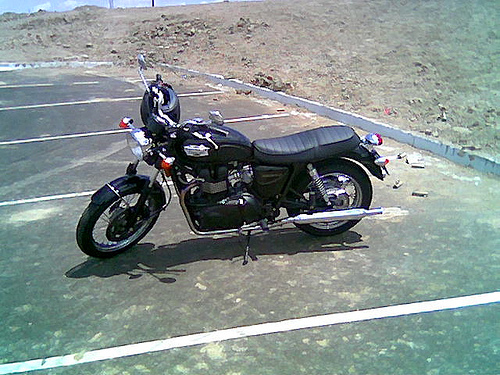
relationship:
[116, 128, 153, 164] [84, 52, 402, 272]
headlight on the bike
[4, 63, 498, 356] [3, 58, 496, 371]
lines in lot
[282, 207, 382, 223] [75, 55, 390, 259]
muffler on bike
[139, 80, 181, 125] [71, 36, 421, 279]
helmet hanging on motorcycle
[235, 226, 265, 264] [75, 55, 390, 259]
kickstand held up by bike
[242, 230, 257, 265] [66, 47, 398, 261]
kickstand holding up bike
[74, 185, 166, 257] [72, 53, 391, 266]
front tire mounted on motorcycle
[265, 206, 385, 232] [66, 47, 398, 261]
muffler on bike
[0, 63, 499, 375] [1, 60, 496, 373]
lines on pavement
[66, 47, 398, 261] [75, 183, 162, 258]
bike has front tire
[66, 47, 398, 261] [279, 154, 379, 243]
bike has tire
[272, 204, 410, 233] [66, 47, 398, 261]
exhaust pipe on bike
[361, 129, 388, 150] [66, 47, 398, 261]
light on bike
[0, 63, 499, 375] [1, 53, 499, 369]
lines on parking lot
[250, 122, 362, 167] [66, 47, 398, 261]
seat on bike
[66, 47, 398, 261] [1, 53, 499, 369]
bike on parking lot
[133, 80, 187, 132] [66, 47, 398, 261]
helmet on bike